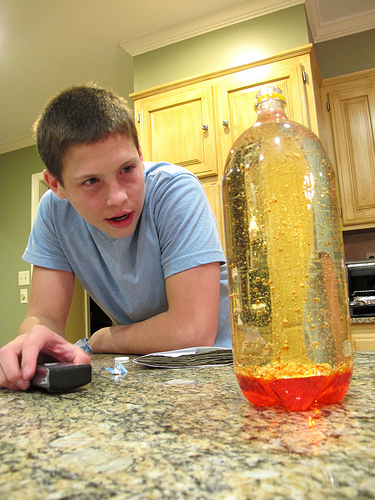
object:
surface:
[0, 350, 375, 500]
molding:
[118, 0, 306, 57]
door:
[129, 78, 224, 179]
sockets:
[20, 288, 28, 304]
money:
[135, 350, 232, 370]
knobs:
[202, 124, 208, 131]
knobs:
[222, 120, 229, 127]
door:
[215, 61, 310, 171]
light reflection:
[227, 47, 272, 93]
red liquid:
[235, 368, 353, 410]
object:
[28, 361, 93, 395]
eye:
[120, 165, 135, 173]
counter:
[0, 348, 375, 500]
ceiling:
[0, 0, 375, 143]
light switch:
[18, 270, 29, 287]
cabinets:
[139, 84, 219, 179]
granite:
[0, 406, 66, 500]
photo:
[1, 0, 374, 500]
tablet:
[114, 356, 130, 363]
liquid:
[220, 110, 352, 411]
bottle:
[221, 83, 355, 411]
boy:
[0, 84, 232, 395]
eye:
[81, 177, 101, 187]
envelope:
[132, 344, 233, 370]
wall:
[0, 142, 88, 345]